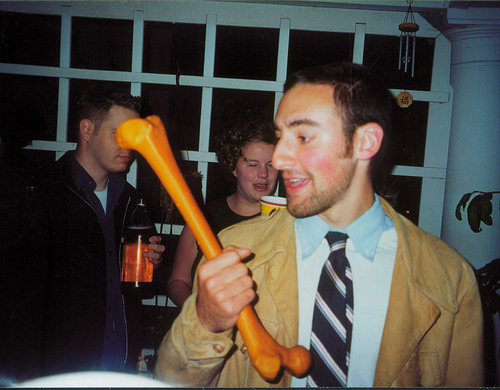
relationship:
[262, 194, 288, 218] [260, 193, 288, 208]
cup has red stripe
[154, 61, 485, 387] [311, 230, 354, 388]
man wears neck tie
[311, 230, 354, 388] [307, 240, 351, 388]
tie has stripe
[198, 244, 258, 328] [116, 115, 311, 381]
fist has bone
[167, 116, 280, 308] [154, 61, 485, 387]
woman behind man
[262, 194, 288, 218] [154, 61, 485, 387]
cup behind man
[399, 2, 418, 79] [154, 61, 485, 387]
windchimes behind man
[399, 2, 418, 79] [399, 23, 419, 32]
windchimes has disc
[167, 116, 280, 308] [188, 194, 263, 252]
woman wearing shirt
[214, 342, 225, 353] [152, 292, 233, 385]
button on sleeve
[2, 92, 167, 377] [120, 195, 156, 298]
man holds bottle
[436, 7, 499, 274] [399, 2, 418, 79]
column next to windchimes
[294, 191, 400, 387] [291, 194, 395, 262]
shirt has collar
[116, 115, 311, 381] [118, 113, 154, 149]
bone has knob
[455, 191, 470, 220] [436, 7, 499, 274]
leaf next to column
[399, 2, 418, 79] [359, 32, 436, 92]
windchimes hangs in window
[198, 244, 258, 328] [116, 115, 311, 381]
hand holds bone